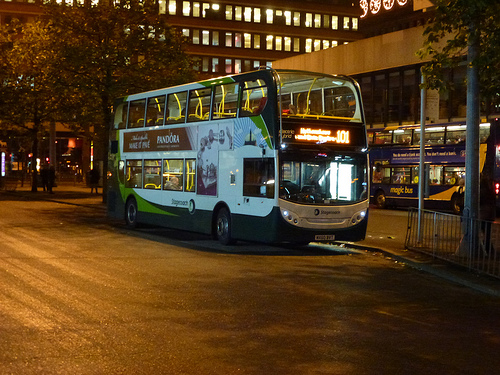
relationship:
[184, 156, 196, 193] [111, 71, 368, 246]
window on a bus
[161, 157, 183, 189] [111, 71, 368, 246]
window on a bus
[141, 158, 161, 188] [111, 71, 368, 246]
window on a bus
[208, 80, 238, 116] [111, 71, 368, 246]
window on a bus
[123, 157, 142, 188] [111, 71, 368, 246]
window on a bus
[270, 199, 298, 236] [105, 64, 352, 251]
headlight on bus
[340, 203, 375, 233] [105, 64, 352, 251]
headlight on bus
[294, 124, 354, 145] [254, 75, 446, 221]
letters on bus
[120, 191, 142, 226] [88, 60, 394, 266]
back wheel on bus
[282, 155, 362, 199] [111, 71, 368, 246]
windshield on bus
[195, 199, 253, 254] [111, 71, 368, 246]
wheel on bus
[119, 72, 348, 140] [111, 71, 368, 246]
top of bus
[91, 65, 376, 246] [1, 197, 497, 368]
bus on road